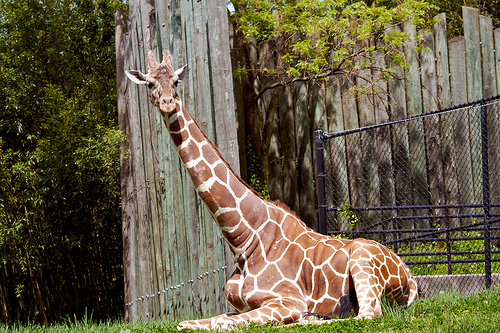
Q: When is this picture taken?
A: While giraffe is sitting.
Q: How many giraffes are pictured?
A: One.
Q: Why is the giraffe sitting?
A: Relaxing.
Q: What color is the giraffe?
A: Tan and white.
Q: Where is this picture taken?
A: Zoo.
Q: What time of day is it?
A: Day time.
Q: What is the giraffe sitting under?
A: Tree.